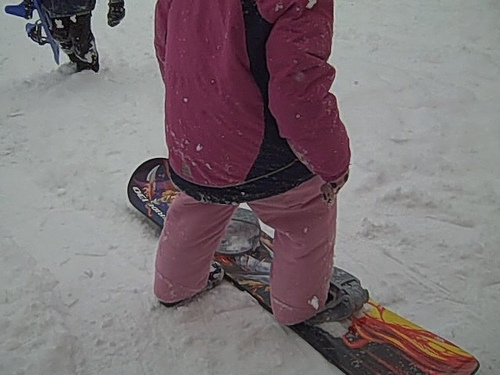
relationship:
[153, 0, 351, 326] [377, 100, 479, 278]
boy in snow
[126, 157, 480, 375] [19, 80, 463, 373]
skate board on ground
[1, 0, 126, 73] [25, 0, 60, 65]
person holding blue snowboard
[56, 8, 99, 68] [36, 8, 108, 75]
snow on dark pants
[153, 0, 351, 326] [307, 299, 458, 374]
boy riding skateboard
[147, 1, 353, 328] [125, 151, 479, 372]
boy riding snowboard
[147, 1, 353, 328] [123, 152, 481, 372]
boy riding skate board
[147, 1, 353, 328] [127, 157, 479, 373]
boy riding snow board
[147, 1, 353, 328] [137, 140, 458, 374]
boy riding skateboard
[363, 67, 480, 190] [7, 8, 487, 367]
snow on ground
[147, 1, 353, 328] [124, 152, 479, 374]
boy riding skateboard